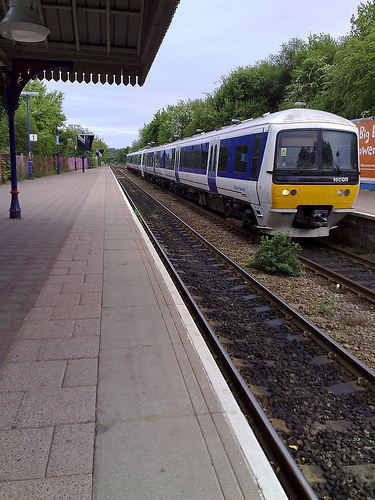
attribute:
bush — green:
[247, 227, 307, 278]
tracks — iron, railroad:
[108, 159, 308, 339]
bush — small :
[254, 232, 300, 277]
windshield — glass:
[271, 125, 363, 188]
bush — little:
[251, 230, 301, 282]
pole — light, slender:
[25, 97, 31, 180]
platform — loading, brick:
[0, 163, 277, 497]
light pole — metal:
[22, 93, 37, 178]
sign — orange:
[347, 116, 374, 182]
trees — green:
[18, 86, 88, 154]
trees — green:
[244, 17, 373, 110]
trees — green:
[147, 98, 271, 131]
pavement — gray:
[2, 183, 248, 480]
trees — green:
[131, 1, 370, 146]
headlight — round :
[280, 185, 292, 201]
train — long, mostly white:
[126, 105, 364, 238]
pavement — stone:
[0, 163, 260, 498]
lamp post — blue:
[20, 88, 44, 180]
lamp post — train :
[74, 130, 94, 180]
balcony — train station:
[40, 157, 151, 452]